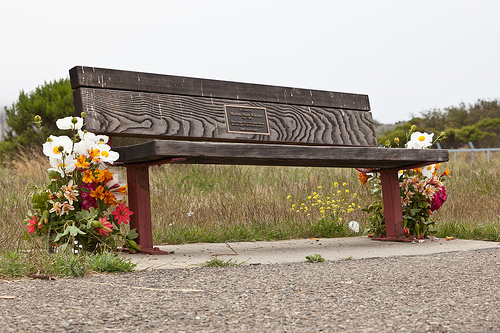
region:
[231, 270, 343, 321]
The pavement is gray.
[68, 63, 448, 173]
The bench is brown.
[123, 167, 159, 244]
The left bench leg is red.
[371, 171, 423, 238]
The right bench leg is red.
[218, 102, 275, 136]
The plaque is on the bench.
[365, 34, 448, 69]
The sky is clear.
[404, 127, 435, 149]
The flower is white and yellow.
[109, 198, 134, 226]
The flower is red.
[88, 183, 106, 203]
The flower is orange.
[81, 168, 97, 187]
The flower is orange.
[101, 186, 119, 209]
The flower is orange.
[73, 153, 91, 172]
The flower is orange.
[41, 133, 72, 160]
The flower is white and yellow.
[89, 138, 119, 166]
The flower is white and yellow.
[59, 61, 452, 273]
The bench is vacant.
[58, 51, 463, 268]
The bench is unoccupied.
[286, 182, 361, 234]
Yellow flowers beneath the bench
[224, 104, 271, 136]
An enscription on the bench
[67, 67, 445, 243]
A bench near the grass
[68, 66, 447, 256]
The bench is wooden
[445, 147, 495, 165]
A fence behind the bench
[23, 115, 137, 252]
Various flowers on the side of the bench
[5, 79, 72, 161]
A tree in the grassy field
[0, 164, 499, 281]
The grass beneath the bench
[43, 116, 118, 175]
White flowers near the bench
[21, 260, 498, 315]
pavement in front of the bench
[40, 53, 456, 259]
a memorial bench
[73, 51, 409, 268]
a bench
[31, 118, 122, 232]
flowers next to the bench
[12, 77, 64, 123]
a tree behind the bench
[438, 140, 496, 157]
a silver fence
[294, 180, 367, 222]
yellow flowers under the bench in the grass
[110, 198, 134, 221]
a pink flower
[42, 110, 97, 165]
white flowers in the bouquet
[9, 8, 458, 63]
the sky behind the bench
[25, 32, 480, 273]
wooden bench placed outdoors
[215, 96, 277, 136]
brass plaque mounted on bench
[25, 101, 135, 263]
flowers at end of bench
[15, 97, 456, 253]
flowers at both ends of bench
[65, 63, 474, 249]
wooden bench on metal legs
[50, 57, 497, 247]
bench sitting on concrete pad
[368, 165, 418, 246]
red iron metal support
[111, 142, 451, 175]
wooden seat of bench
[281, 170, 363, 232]
yellow flowers growing in grass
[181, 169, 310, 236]
wild grass growing in field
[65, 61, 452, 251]
wooden bench with a plaque on it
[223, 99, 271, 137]
plaque on the wooden bench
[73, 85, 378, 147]
wooden slat of bench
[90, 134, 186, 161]
wooden slat of bench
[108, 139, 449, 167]
wooden slat of bench seat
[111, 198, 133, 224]
red flower next to wooden bench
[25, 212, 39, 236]
red flower next to wooden bench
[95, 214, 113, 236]
red flower next to wooden bench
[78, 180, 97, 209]
red flower next to wooden bench